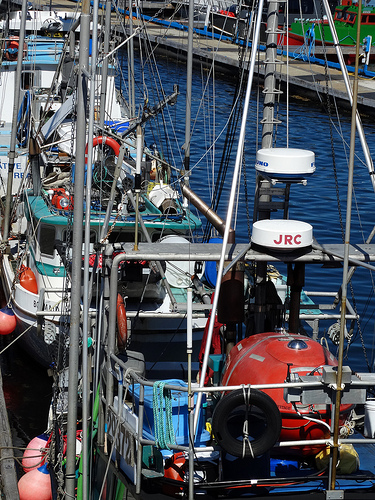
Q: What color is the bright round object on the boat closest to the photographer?
A: Orange.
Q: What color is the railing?
A: Silver.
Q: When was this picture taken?
A: Daytime.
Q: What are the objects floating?
A: Boats.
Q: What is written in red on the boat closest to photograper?
A: JRC.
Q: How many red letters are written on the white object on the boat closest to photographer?
A: 3.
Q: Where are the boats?
A: Water.